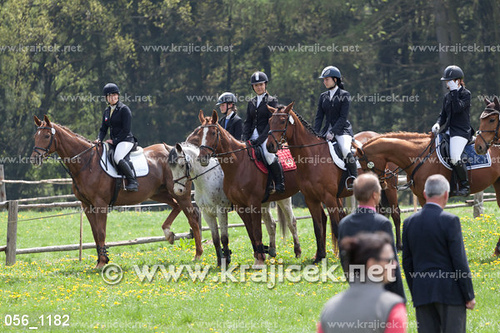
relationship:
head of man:
[337, 198, 447, 330] [307, 190, 427, 327]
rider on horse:
[75, 74, 163, 163] [29, 130, 196, 255]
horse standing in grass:
[36, 120, 217, 261] [6, 202, 498, 323]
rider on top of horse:
[91, 81, 139, 192] [31, 112, 201, 272]